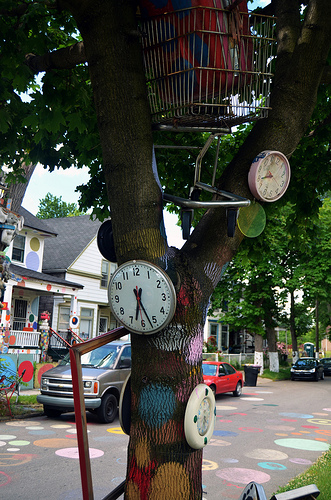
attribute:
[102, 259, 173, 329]
clock — white, round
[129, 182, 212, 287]
tree — painted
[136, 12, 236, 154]
basket — metal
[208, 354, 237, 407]
car — red, parked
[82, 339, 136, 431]
van — silver, parked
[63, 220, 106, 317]
house — white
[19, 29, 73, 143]
trees — green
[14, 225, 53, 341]
house — white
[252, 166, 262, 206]
metal — pink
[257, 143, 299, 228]
clock — round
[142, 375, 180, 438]
circle — blue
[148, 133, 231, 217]
cart — metal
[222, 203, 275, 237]
circle — yellow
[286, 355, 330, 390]
car — black, parked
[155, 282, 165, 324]
numbers — black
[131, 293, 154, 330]
hands — black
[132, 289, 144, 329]
hand — red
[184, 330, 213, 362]
circle — pink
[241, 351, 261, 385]
can — black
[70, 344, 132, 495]
frame — red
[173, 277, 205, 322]
circle — red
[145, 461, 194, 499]
circle — yellow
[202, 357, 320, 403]
cars — parked